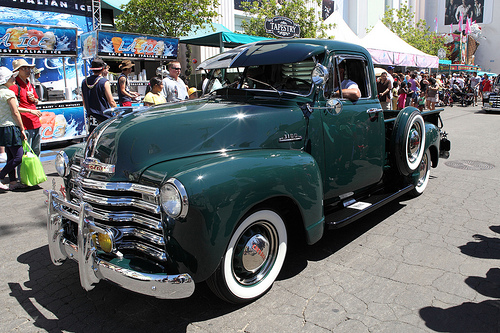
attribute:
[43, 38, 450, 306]
car — old fashioned, shiny, green, antique, vintage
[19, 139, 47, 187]
bag — neon green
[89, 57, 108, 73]
baseball cap — backwards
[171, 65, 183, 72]
sunglasses — dark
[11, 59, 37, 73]
hat — brown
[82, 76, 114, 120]
shirt — blue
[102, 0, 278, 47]
awning — blue, turquoise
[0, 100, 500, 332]
road — cracked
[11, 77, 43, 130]
shirt — red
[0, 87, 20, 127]
shirt — white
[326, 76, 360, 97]
shirt — white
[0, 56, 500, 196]
people — walking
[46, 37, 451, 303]
truck — green